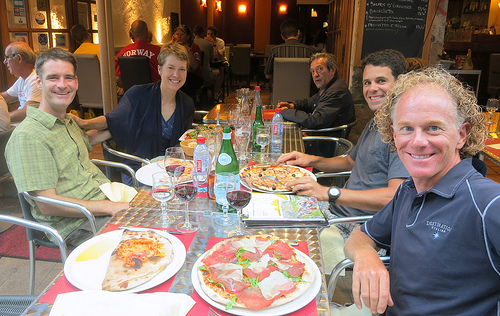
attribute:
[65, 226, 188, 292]
plate — white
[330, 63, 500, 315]
man — balding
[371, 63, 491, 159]
hair — curly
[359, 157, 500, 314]
shirt — blue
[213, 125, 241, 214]
bottle — green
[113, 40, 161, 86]
shirt — red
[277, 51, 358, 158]
man — annoyed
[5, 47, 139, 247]
man — smiling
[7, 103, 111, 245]
shirt — striped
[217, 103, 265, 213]
bottles — green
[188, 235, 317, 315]
mat — red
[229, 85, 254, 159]
glasses — empty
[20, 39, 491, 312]
people — eating, sitting